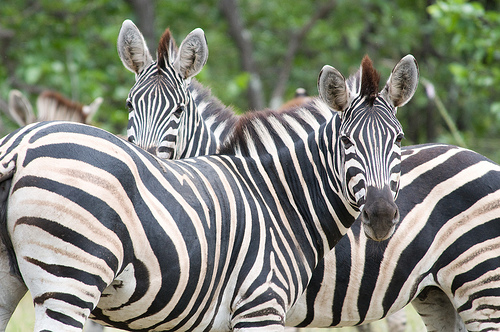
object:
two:
[1, 21, 498, 329]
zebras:
[0, 16, 500, 332]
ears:
[114, 18, 153, 75]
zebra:
[114, 17, 499, 332]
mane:
[35, 87, 86, 122]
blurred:
[0, 0, 500, 166]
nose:
[362, 197, 400, 225]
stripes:
[147, 83, 159, 131]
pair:
[341, 133, 403, 147]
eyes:
[339, 134, 356, 150]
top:
[317, 53, 420, 109]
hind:
[7, 155, 124, 332]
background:
[1, 2, 499, 163]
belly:
[98, 266, 240, 329]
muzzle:
[363, 188, 399, 242]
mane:
[155, 27, 239, 147]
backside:
[0, 121, 146, 329]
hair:
[353, 53, 383, 106]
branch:
[208, 0, 268, 107]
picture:
[0, 1, 499, 329]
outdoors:
[3, 2, 500, 331]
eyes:
[172, 105, 186, 119]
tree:
[192, 0, 351, 115]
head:
[4, 86, 106, 128]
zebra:
[5, 86, 131, 138]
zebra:
[0, 50, 421, 332]